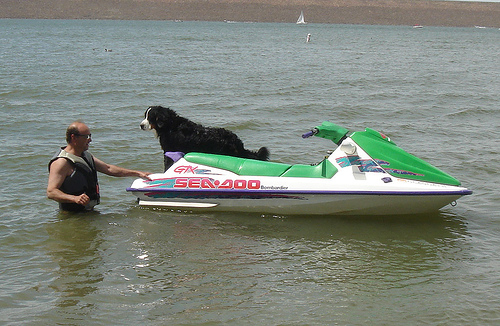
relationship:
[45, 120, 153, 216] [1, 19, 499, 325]
man in lake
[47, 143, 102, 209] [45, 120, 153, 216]
lifejacket on man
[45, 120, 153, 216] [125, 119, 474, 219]
man and ski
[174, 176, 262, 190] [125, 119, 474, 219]
lettering on ski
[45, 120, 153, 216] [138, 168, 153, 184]
man has hand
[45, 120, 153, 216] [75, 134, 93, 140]
man wearing glasses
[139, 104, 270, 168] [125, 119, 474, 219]
dog on ski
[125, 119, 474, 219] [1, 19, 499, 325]
ski in lake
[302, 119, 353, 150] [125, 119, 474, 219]
bar on ski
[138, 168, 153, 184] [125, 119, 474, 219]
hand on ski